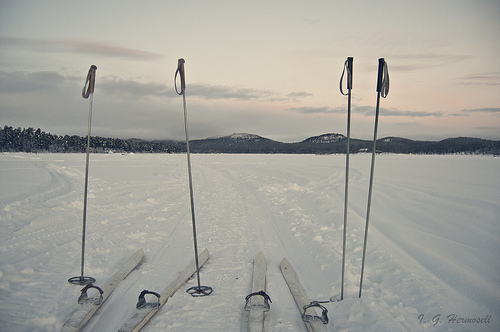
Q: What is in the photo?
A: Snow.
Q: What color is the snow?
A: White.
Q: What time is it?
A: Evening.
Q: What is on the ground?
A: Skis.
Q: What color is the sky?
A: Orange and grey.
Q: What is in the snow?
A: Tracks.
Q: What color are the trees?
A: Green.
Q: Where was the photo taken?
A: Outdoors somewhere.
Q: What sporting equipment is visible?
A: Skis.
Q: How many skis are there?
A: 4.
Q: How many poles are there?
A: 4.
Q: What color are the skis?
A: White.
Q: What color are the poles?
A: Black.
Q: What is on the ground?
A: Snow.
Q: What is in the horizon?
A: Hills.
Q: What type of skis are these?
A: Cross country.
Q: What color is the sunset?
A: Orange and gray.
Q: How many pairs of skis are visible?
A: 2.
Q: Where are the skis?
A: In the snow.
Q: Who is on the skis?
A: Nobody.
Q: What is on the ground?
A: Snow.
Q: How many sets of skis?
A: 2.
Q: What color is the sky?
A: Pink.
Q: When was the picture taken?
A: Evening.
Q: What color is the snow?
A: White.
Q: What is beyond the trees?
A: Mountains.